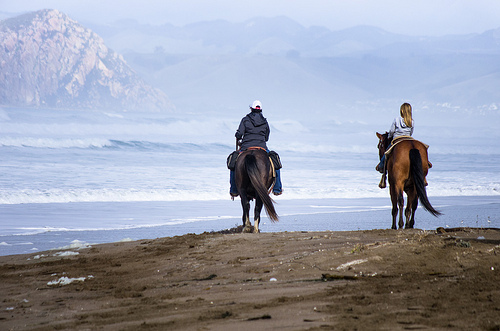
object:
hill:
[0, 7, 175, 112]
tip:
[32, 7, 62, 17]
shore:
[0, 225, 499, 330]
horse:
[233, 148, 279, 234]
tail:
[243, 154, 281, 223]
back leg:
[237, 178, 253, 233]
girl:
[375, 102, 416, 174]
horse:
[374, 130, 430, 230]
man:
[228, 99, 282, 198]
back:
[241, 113, 269, 147]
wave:
[0, 137, 499, 164]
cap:
[249, 100, 264, 110]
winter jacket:
[235, 112, 272, 152]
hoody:
[387, 116, 416, 140]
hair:
[399, 102, 414, 128]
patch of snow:
[45, 270, 94, 286]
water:
[0, 105, 500, 257]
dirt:
[0, 224, 499, 331]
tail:
[407, 147, 446, 219]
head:
[375, 131, 393, 162]